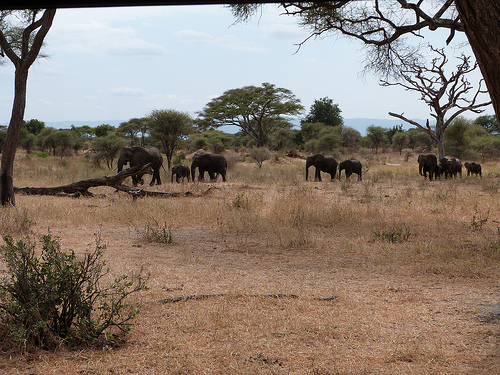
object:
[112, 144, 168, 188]
elephant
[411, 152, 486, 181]
group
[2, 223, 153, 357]
bush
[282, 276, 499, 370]
ground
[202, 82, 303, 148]
tree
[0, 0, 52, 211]
trunk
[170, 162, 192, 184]
elephant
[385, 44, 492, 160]
tree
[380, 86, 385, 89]
leaves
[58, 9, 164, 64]
cloud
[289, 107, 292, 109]
leaves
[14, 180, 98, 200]
trunk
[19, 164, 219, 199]
fallen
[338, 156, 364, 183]
elephants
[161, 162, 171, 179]
tail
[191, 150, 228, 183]
elephant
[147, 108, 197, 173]
trees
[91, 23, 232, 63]
sky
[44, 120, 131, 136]
mountain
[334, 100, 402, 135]
distance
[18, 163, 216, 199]
limb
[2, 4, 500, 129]
background